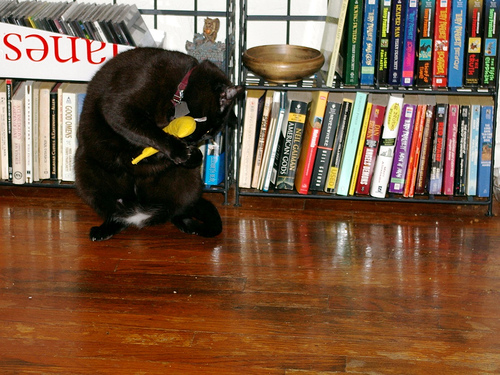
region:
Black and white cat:
[39, 38, 256, 265]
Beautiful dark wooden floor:
[4, 185, 497, 374]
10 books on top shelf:
[334, 0, 498, 96]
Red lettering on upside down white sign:
[4, 20, 136, 80]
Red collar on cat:
[157, 58, 208, 128]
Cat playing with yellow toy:
[124, 102, 228, 174]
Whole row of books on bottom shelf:
[237, 92, 499, 209]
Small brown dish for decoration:
[244, 33, 334, 91]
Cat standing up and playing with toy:
[69, 32, 257, 242]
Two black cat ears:
[218, 77, 250, 142]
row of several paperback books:
[243, 93, 495, 200]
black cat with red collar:
[66, 43, 241, 250]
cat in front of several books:
[32, 37, 273, 239]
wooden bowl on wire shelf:
[236, 33, 325, 85]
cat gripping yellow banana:
[73, 43, 237, 238]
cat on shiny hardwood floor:
[77, 41, 233, 358]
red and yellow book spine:
[299, 90, 331, 203]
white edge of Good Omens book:
[60, 86, 77, 183]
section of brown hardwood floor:
[13, 247, 480, 367]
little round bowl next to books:
[249, 8, 414, 87]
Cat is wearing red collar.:
[167, 70, 204, 101]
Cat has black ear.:
[216, 75, 255, 113]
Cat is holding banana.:
[136, 95, 219, 186]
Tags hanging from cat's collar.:
[168, 90, 194, 131]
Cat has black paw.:
[79, 207, 159, 276]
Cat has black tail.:
[196, 195, 242, 262]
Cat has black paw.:
[148, 128, 229, 208]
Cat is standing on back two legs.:
[69, 152, 226, 258]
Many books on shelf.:
[280, 86, 436, 153]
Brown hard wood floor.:
[146, 273, 394, 358]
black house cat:
[75, 48, 234, 240]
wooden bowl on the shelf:
[243, 43, 324, 83]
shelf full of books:
[233, 91, 493, 193]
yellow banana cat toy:
[130, 115, 195, 166]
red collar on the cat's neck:
[172, 68, 193, 104]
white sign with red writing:
[0, 23, 127, 79]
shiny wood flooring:
[2, 188, 494, 374]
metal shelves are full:
[0, 1, 495, 213]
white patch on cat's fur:
[114, 207, 155, 227]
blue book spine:
[450, 0, 467, 90]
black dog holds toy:
[78, 12, 249, 274]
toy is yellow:
[105, 112, 202, 187]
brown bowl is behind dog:
[247, 34, 323, 82]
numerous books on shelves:
[215, 9, 497, 201]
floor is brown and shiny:
[50, 234, 464, 373]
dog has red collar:
[167, 62, 222, 119]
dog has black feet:
[82, 205, 134, 257]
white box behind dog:
[1, 23, 118, 73]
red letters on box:
[5, 29, 122, 68]